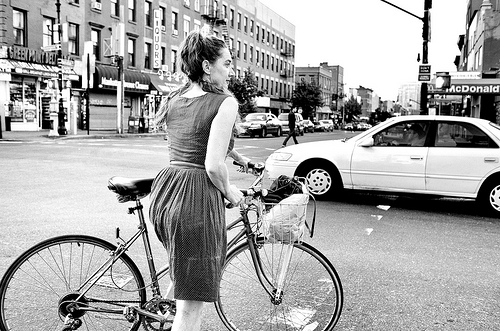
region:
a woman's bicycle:
[0, 159, 345, 329]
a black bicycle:
[105, 174, 158, 204]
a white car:
[264, 114, 499, 217]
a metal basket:
[244, 172, 316, 247]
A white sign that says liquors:
[152, 9, 162, 69]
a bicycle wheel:
[212, 234, 344, 329]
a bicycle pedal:
[122, 302, 167, 324]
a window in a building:
[9, 6, 29, 48]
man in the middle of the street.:
[281, 109, 301, 146]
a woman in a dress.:
[147, 27, 254, 329]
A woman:
[155, 28, 273, 329]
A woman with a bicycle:
[12, 25, 344, 325]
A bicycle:
[5, 163, 386, 329]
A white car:
[264, 95, 496, 240]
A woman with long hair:
[166, 20, 266, 154]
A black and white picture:
[3, 8, 482, 323]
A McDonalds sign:
[428, 65, 498, 100]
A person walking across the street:
[283, 94, 307, 151]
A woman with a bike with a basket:
[89, 37, 344, 329]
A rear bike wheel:
[5, 234, 142, 329]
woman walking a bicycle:
[9, 29, 339, 329]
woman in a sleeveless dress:
[152, 26, 251, 329]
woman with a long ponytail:
[148, 25, 236, 137]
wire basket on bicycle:
[245, 163, 318, 252]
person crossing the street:
[280, 101, 302, 148]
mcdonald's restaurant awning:
[419, 71, 498, 98]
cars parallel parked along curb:
[242, 111, 338, 135]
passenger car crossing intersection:
[272, 106, 499, 220]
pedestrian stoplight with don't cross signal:
[425, 69, 456, 96]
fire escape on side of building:
[197, 0, 230, 60]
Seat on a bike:
[103, 168, 183, 197]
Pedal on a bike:
[111, 291, 208, 327]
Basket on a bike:
[237, 178, 324, 273]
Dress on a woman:
[151, 84, 256, 303]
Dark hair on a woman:
[167, 24, 243, 94]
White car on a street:
[301, 101, 481, 217]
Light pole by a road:
[404, 0, 450, 112]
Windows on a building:
[12, 4, 293, 87]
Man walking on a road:
[276, 104, 308, 146]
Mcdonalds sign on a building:
[431, 67, 498, 103]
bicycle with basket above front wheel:
[0, 162, 355, 329]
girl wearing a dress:
[148, 29, 273, 326]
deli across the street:
[4, 40, 68, 139]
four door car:
[256, 110, 499, 221]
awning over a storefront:
[92, 60, 156, 96]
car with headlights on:
[341, 119, 358, 133]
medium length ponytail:
[174, 25, 229, 97]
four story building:
[234, 11, 291, 141]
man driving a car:
[401, 123, 428, 153]